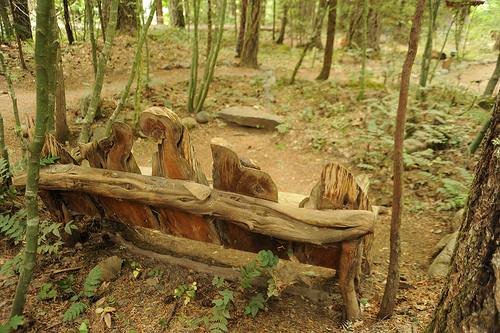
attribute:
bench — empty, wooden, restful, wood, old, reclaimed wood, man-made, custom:
[11, 101, 380, 331]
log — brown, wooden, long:
[15, 162, 377, 247]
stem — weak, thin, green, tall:
[103, 0, 163, 137]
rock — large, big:
[215, 105, 283, 131]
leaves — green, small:
[61, 298, 88, 321]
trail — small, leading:
[0, 43, 495, 146]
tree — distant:
[103, 0, 141, 36]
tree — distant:
[12, 0, 37, 39]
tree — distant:
[166, 0, 186, 28]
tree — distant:
[345, 0, 381, 56]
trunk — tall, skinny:
[378, 0, 426, 316]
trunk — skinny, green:
[6, 0, 57, 325]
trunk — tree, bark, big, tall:
[424, 93, 500, 331]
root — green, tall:
[1, 51, 28, 139]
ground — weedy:
[1, 26, 500, 331]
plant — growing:
[188, 246, 277, 332]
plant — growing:
[52, 258, 105, 324]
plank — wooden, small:
[291, 163, 374, 267]